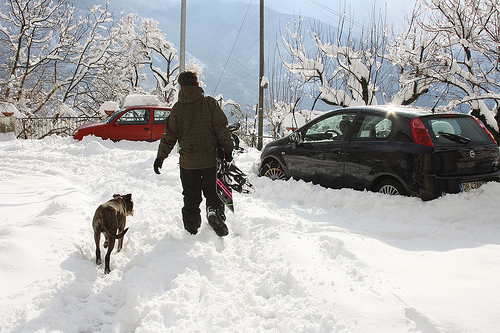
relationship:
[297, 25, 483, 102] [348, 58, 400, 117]
trees covered snow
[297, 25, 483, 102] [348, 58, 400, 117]
trees covered with snow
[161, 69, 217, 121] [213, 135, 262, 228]
man with snowboard